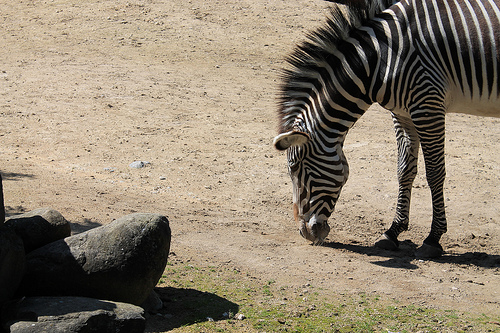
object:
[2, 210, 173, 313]
boulder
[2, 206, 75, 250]
boulder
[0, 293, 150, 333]
boulder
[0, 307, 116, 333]
boulder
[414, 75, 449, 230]
leg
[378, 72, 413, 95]
stripes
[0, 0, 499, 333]
brown dirt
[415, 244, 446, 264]
hoove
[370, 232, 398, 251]
hoove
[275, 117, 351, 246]
head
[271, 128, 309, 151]
ear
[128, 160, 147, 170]
rock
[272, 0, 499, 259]
zebra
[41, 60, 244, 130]
street sign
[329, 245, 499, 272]
shadow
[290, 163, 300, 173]
eye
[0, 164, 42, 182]
shadow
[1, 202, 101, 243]
shadow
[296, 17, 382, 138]
wide stripes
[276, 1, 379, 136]
hair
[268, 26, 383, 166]
neck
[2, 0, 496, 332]
ground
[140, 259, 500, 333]
grass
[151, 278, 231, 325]
shadow